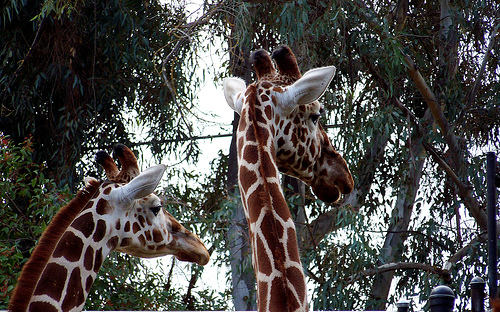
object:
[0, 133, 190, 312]
bushes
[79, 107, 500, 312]
fence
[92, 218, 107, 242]
spot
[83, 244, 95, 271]
spot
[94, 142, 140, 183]
horns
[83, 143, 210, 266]
head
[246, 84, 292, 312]
mane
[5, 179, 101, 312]
mane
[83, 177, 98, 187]
ears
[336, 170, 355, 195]
giraffe nose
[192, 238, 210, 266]
giraffe nose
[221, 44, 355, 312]
giraffe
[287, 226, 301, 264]
spot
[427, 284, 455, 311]
post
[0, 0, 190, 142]
trees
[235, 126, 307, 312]
neck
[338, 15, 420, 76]
two necks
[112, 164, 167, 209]
ear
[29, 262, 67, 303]
spot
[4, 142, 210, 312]
giraffe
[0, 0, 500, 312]
leaves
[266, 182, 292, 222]
spot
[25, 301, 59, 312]
spots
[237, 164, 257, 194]
spots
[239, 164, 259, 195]
brown spot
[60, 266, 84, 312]
spot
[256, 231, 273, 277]
spot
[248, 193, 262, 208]
brown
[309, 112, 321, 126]
eye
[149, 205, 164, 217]
eye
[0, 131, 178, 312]
flowers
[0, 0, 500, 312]
area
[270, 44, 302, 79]
horn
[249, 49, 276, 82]
horn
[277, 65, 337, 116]
ear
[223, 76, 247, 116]
ear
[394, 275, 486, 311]
fence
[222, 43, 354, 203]
head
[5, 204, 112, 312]
necks